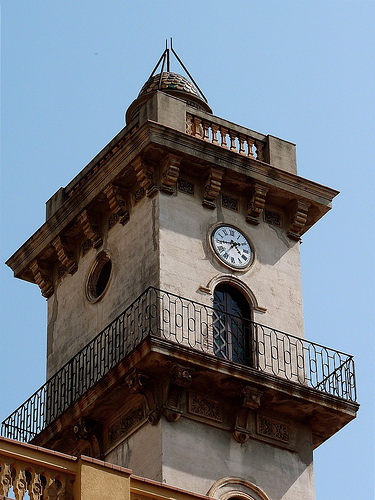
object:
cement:
[117, 415, 313, 499]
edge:
[162, 461, 212, 485]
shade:
[157, 414, 309, 479]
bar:
[253, 322, 264, 371]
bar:
[348, 351, 357, 402]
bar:
[146, 285, 157, 335]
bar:
[124, 305, 135, 353]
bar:
[269, 328, 282, 375]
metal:
[1, 285, 356, 443]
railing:
[190, 114, 263, 163]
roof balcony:
[157, 95, 296, 172]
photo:
[0, 0, 375, 497]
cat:
[144, 281, 356, 356]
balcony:
[2, 283, 360, 469]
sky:
[1, 2, 371, 498]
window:
[200, 286, 254, 363]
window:
[85, 250, 113, 303]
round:
[202, 475, 289, 499]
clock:
[209, 221, 254, 272]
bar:
[151, 285, 162, 337]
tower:
[1, 36, 358, 497]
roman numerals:
[229, 256, 234, 261]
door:
[201, 273, 265, 371]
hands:
[235, 244, 243, 254]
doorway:
[206, 473, 287, 498]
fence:
[2, 283, 355, 441]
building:
[1, 38, 361, 498]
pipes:
[141, 35, 209, 103]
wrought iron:
[146, 284, 357, 404]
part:
[1, 436, 207, 495]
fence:
[1, 434, 231, 498]